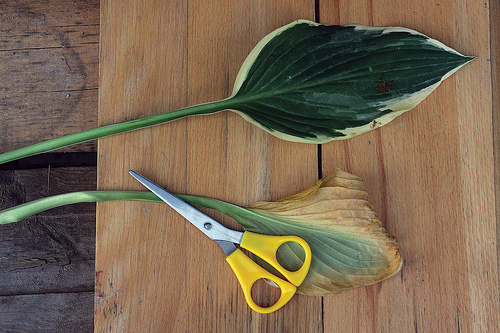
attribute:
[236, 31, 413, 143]
leaf — brown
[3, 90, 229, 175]
stem — green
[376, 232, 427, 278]
screw — metal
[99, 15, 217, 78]
board — weather worn, dark, brown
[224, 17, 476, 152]
water — green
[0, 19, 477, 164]
leaf — Dark, Green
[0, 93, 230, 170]
stem — thick, green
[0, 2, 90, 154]
spot — wood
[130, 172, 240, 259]
edge — silver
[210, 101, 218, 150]
wall — yellow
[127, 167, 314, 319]
scissors — yellow, metal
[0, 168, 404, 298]
leaf — smaller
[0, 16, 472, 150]
leaf — green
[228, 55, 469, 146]
edging — white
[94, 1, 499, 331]
boards — light brown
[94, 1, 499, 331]
wood — brown